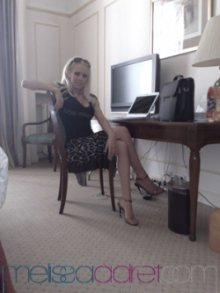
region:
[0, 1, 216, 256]
a slightly blurry view of a woman in a room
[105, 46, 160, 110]
a flat screen television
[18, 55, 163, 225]
woman sitting in a chair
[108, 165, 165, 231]
woman wearing high heeled shoes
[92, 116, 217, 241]
table beside woman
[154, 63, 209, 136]
laptop bag on table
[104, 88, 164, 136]
white laptop on table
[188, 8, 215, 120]
lamp with large shade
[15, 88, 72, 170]
chair sitting near wall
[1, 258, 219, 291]
website address on bottom of image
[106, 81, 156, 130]
white laptop on desk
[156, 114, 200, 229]
trash can under the desk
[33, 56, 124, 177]
woman wears leopard print skirt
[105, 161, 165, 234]
woman wears high-heels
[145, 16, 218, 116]
partial view of lamp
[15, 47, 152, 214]
woman sits on wooden chair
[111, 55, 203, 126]
briefcase next to laptop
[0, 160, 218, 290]
tan-colored carpet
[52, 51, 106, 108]
woman wears sunglasses on her head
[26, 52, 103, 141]
woman wears black tank top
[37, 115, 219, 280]
the picture is blurry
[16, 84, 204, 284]
picture taken indoors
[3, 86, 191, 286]
picture taken during the day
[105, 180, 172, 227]
the woman is wearing heals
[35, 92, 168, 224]
the woman is sitting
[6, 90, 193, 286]
a hotel room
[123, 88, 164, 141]
a white laptop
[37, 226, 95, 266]
the carpet is light tan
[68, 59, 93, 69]
she has sunglasses on her head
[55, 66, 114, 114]
her hair is blonde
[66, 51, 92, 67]
pair of black sunglasses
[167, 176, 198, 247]
a black trashcan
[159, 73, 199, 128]
black leather bag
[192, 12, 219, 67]
a white lamp shade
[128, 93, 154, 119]
a white ipad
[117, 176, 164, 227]
a pair of high heels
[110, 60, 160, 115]
a flat screen tv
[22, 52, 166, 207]
a blonde sitting down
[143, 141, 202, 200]
a bunch of eletrical cords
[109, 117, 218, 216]
brown wooden table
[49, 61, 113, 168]
The lady is sitting in the chair.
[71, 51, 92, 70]
Sunglasses on top of the lady head.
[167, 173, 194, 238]
A garbage can sits uner the table.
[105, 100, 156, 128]
A laptop is sitting on the table.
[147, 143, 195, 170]
Wires under the table.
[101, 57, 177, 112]
A television is sitting on the desk.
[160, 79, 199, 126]
The briefcase is on the desk.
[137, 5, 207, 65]
A picture on the wall.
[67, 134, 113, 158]
The woman is wearing a printed skirt.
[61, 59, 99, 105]
The woman has long blonde hair